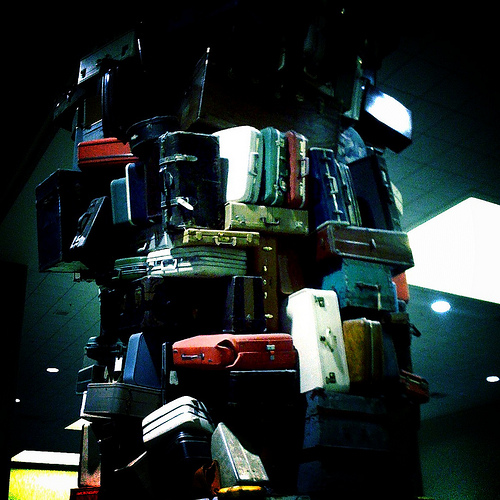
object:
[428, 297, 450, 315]
light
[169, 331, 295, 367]
suitcase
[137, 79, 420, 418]
stack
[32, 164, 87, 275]
trunk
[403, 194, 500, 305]
light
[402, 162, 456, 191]
tile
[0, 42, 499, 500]
ceiling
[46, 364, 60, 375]
vents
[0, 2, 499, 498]
background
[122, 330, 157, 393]
luggage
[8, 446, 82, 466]
door